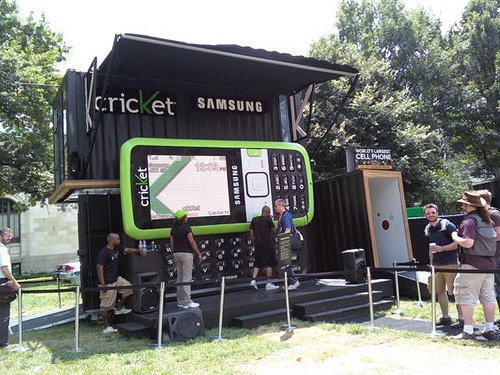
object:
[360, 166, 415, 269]
doorway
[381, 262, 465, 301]
ramp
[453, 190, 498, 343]
man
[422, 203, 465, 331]
man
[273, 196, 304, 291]
man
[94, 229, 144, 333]
man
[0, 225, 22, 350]
man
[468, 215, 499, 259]
backpack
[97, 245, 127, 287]
shirt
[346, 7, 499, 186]
tree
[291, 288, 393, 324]
steps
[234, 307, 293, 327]
steps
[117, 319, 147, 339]
steps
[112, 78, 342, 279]
black speaker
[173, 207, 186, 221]
cap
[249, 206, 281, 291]
man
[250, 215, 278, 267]
clothes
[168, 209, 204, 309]
woman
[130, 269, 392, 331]
platform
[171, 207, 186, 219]
bandana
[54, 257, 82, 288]
car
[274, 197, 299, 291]
man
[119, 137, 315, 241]
sign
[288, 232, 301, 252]
bag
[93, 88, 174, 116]
sign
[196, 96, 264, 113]
sign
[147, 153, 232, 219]
screen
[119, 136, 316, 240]
phone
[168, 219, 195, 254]
shirt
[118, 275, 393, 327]
stage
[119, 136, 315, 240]
cellphone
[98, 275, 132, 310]
pants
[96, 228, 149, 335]
man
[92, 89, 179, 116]
cricket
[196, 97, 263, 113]
samsung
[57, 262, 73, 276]
back end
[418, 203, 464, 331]
man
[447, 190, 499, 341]
man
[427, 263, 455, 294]
shorts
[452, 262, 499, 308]
shorts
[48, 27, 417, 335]
phone shop